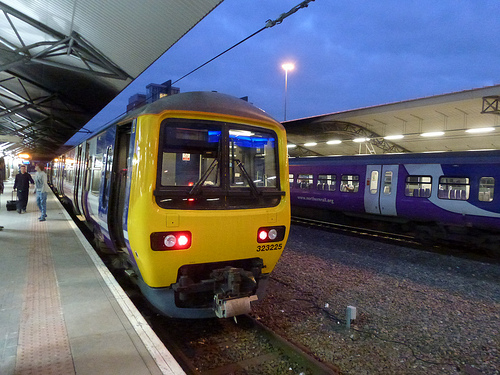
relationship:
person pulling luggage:
[12, 163, 36, 214] [7, 188, 21, 212]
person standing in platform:
[34, 166, 49, 221] [0, 172, 203, 375]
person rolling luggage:
[12, 163, 34, 216] [5, 188, 19, 213]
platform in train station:
[2, 180, 165, 373] [5, 90, 493, 369]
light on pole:
[277, 58, 296, 74] [281, 74, 288, 124]